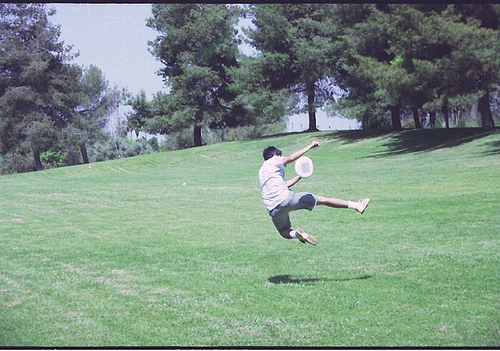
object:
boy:
[258, 140, 370, 244]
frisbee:
[293, 156, 314, 179]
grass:
[0, 128, 499, 350]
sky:
[0, 0, 365, 143]